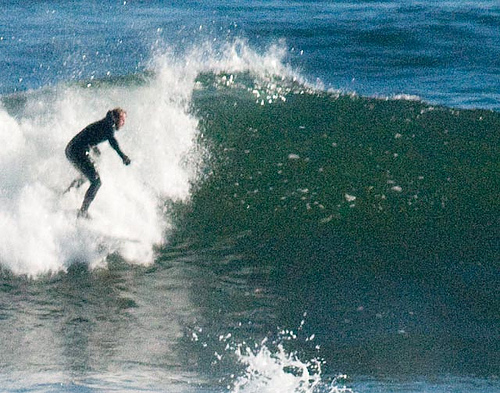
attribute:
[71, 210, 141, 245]
surfboard — white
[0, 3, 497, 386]
water — blue, green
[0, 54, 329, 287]
water — white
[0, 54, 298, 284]
wave — white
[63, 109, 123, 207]
wetsuit — black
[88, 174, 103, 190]
knee — bent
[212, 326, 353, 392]
water — white, splashing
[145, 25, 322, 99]
water — white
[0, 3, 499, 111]
water — still, blue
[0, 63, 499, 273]
water wall — green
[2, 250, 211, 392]
reflection — white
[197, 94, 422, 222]
dots — white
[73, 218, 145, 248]
surfboard — white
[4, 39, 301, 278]
wave — white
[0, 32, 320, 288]
wave — white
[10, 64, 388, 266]
wave — huge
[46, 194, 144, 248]
surfboard — white, barely visible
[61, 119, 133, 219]
swimsuit — black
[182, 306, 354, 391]
foam — white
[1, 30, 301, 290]
foam — huge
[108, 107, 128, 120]
hair — blonde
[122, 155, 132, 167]
hand — outstretched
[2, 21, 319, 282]
foam — white